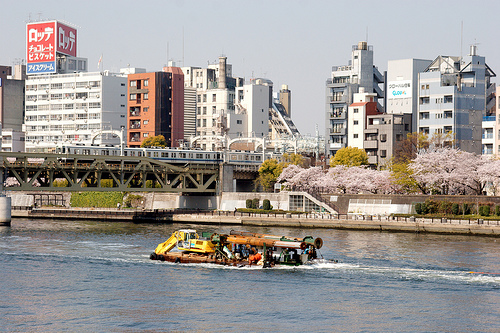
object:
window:
[88, 79, 102, 86]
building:
[322, 34, 387, 172]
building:
[414, 51, 486, 162]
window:
[76, 81, 87, 88]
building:
[7, 64, 139, 176]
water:
[17, 210, 492, 331]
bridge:
[0, 148, 267, 195]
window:
[414, 91, 434, 109]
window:
[137, 75, 155, 90]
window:
[480, 125, 494, 142]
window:
[127, 115, 144, 133]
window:
[331, 72, 349, 87]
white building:
[338, 82, 398, 167]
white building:
[191, 75, 272, 149]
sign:
[26, 20, 78, 72]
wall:
[6, 190, 499, 236]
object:
[247, 252, 262, 263]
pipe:
[227, 233, 322, 254]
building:
[124, 64, 185, 144]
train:
[59, 143, 276, 161]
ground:
[399, 95, 421, 140]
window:
[89, 91, 103, 97]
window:
[87, 79, 100, 88]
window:
[85, 101, 99, 108]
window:
[61, 112, 76, 121]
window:
[50, 113, 60, 122]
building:
[359, 109, 414, 169]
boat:
[142, 225, 329, 278]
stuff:
[155, 231, 268, 251]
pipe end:
[300, 236, 327, 249]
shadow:
[174, 193, 219, 212]